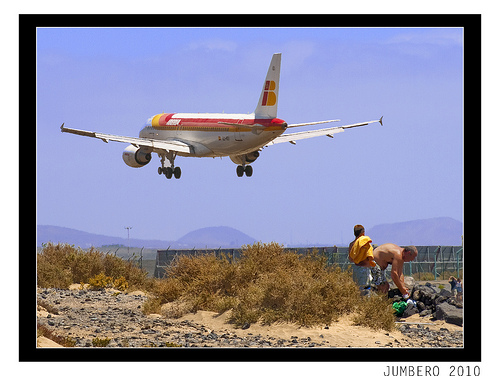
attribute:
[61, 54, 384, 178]
airplane — flying, low, orange, red, taking off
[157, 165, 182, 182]
landing gear — down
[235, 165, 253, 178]
landing gear — down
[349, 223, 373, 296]
man — standing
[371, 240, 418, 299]
man — standing, shirtless, bending, older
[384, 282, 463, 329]
rocks — black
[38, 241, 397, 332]
foliage — brown, green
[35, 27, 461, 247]
sky — blue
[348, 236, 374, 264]
shirt — yellow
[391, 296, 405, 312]
cloth — green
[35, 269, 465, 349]
beach — sandy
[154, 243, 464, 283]
fence — tall